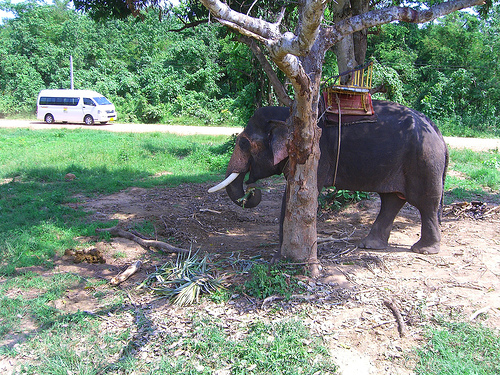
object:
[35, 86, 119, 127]
car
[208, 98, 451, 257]
elephant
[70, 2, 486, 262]
tree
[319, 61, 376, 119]
saddle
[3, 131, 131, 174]
grass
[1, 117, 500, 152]
road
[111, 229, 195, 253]
branches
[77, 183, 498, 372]
ground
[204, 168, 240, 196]
tusk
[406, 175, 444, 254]
leg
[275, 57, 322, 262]
trunk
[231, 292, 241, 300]
rock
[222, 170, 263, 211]
trunk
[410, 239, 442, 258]
foot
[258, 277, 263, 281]
leaves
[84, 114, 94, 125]
wheel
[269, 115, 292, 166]
ear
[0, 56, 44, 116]
trees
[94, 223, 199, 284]
root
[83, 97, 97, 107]
windows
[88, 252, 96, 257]
feces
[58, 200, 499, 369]
dirt